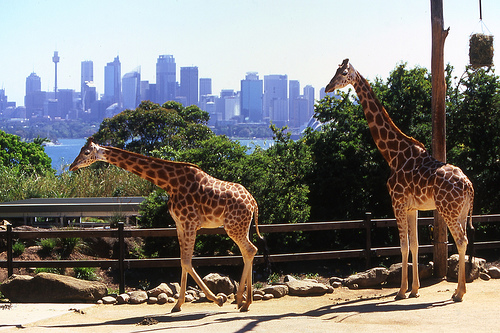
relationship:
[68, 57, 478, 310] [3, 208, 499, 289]
giraffes in fence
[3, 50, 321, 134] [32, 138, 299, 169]
buildings by water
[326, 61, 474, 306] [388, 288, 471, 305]
giraffe has feet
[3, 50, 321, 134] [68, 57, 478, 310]
buildings behind giraffes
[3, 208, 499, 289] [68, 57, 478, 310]
fence behind giraffes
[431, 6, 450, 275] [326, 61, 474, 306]
pole behind giraffe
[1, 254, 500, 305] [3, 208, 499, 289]
rocks by fence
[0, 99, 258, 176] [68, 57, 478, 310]
trees behind giraffes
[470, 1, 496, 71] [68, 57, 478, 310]
feeder behind giraffes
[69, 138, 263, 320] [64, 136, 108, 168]
giraffe has head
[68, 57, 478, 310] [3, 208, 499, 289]
giraffes behind fence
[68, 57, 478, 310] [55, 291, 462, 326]
giraffes have shadows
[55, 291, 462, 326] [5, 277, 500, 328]
shadows on ground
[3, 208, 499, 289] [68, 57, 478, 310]
fence surround giraffes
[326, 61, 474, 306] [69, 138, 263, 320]
giraffe behind giraffe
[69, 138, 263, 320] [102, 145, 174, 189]
giraffe has neck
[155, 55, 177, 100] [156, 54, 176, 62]
building has roof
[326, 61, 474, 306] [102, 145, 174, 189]
giraffe has neck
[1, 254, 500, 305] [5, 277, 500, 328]
rocks on ground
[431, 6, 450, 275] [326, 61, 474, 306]
pole beside giraffe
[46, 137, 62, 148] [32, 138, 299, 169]
boat on water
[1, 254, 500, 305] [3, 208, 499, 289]
rocks beside fence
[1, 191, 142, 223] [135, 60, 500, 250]
tracks in bushes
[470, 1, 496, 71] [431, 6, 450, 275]
feeder on pole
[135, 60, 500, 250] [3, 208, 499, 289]
bushes behind fence